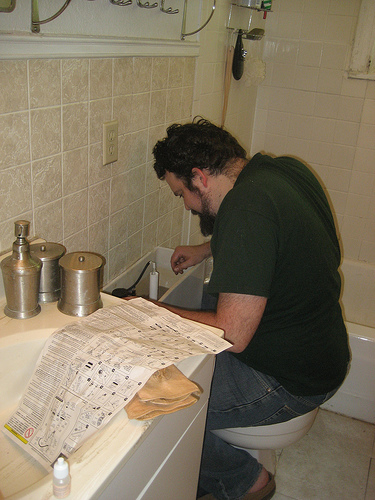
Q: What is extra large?
A: Instruction paper.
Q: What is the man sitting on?
A: A toilet.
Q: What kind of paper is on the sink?
A: Instructions.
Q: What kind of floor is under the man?
A: Tile.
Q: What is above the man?
A: Hangers.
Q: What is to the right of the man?
A: A bathtub.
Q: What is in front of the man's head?
A: An electrical outlet.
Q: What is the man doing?
A: Repairing a toilet.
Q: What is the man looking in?
A: Inside the toilet.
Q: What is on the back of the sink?
A: Steel containers.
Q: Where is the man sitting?
A: On a toilet.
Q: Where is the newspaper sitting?
A: On the counter.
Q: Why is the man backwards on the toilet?
A: Fixing it.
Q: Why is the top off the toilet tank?
A: Being fixed.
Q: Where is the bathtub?
A: On the left.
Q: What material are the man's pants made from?
A: Denim.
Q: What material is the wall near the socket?
A: Tile.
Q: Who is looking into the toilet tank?
A: The man.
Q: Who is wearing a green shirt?
A: The man on the toilet.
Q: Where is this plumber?
A: On the toilet.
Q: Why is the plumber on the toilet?
A: He is fixing something.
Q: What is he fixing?
A: The flush chain.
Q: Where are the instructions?
A: On the sink.